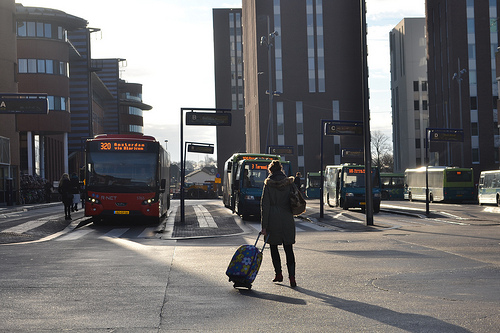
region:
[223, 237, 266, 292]
a floral suitcase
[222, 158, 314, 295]
a woman walking with a floral suitcase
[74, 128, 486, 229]
several buses on the road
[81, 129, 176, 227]
a red bus waiting for passengers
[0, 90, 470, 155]
bus stop signs for the buses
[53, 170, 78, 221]
a person getting onto the bus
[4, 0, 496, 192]
several large buildings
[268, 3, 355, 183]
lines of windows on one of the buildings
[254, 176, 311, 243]
the woman has a fur lined coat on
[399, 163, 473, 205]
this bus is dark green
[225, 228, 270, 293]
Flowered luggage in the forefront.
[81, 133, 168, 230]
Red bus on the street.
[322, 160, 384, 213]
Blue bus on the street.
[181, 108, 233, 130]
Street sign on the post.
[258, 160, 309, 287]
Woman in a long coat.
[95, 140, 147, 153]
Orange lights on the front of the bus.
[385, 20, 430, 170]
Gray building in the background.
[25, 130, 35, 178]
White post on the front of the building.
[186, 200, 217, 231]
Double white lines on the street.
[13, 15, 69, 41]
Windows in the building.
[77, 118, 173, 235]
A red bus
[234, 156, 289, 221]
A small blue bus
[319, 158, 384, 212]
A small blue bus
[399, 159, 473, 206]
A yellow and blue bus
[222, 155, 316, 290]
A woman with a suitcase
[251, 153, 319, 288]
A woman wearing a coat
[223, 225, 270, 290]
A suitcase with flowers on it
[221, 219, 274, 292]
A rolling suitcase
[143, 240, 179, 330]
A crack in the street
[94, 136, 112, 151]
The number 320 on the bus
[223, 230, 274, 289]
a colorful flower suitcase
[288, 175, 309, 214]
a large brown handbag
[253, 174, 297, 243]
a woman's long green coat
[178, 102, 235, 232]
a tall black sign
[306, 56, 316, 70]
the window of a building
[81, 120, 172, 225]
a large red bus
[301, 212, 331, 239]
a white street marking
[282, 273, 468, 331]
the shadow of a woman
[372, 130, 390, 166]
a tall tree with no leaves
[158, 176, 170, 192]
a side mirror of a bus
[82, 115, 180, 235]
City bus on paved road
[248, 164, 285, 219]
City bus on paved road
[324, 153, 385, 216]
City bus on paved road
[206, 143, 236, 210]
City bus on paved road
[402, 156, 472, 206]
City bus on paved road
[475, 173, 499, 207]
City bus on paved road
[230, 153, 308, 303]
Woman walking with rolling luggage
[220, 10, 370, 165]
Tall buildings in background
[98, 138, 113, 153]
Bus number 320 on front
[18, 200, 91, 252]
White lines painted on road